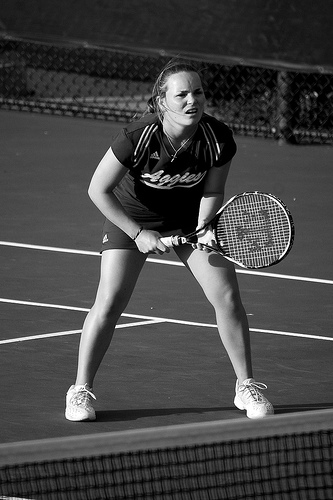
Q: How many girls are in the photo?
A: One.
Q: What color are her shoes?
A: White.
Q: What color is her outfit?
A: Black.